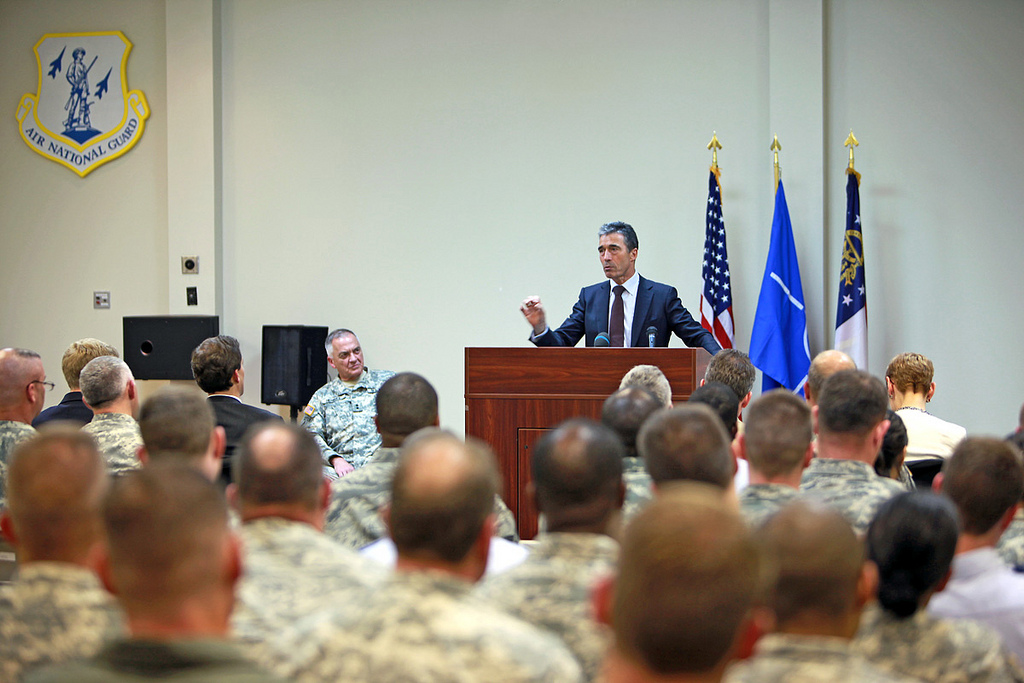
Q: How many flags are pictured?
A: Three.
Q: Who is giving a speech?
A: Man in suit.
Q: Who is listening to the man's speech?
A: Soldiers.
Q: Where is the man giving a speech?
A: Behind a podium.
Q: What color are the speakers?
A: Black.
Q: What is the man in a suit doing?
A: Giving a speech.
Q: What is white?
A: The wall.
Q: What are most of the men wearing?
A: Uniforms.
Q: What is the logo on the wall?
A: Crest.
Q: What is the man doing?
A: Speaking.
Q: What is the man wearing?
A: Suit.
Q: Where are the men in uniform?
A: All over.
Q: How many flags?
A: Three.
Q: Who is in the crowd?
A: A group of soldiers.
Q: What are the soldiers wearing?
A: Camouflage.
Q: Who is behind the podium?
A: The man in the suit.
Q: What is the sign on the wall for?
A: The Air National Guard.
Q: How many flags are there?
A: Three.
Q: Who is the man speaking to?
A: A crowd of soldiers.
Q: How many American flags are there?
A: One.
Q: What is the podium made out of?
A: Wood.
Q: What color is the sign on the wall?
A: Yellow, white, and blue.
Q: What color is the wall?
A: White.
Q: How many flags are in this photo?
A: 3.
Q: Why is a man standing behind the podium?
A: He is giving a speech.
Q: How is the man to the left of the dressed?
A: In an army uniform.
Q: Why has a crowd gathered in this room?
A: To listen to a speech.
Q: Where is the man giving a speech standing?
A: Behind a podium.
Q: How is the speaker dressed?
A: In a suit and tie.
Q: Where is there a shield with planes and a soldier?
A: In the top left corner of the photo.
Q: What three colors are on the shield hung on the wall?
A: Black, yellow, and white.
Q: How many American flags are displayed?
A: 1.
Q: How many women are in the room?
A: 0.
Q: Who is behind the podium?
A: A man in a suit.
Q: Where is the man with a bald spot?
A: In the audience.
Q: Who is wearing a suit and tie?
A: The man behind the podium.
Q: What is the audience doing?
A: Listening to the man speaking.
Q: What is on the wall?
A: The Air National Guard crest.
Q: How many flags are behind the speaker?
A: Three.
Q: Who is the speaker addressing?
A: The audience.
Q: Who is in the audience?
A: Soldiers of the United States of America.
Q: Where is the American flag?
A: Behind the man at the podium.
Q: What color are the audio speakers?
A: Black.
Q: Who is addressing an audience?
A: A man.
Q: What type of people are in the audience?
A: Military.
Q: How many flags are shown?
A: Three.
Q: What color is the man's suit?
A: Blue.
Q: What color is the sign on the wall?
A: Yellow, white and blue.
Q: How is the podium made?
A: Of wood.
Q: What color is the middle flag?
A: Teal.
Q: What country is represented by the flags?
A: America.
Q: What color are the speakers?
A: Black.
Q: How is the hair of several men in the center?
A: Balding.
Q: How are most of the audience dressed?
A: In camouflage.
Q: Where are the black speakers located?
A: On the left near the wall.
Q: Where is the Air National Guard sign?
A: On the wall.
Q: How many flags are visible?
A: Three.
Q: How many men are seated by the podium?
A: One.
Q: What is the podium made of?
A: Wood.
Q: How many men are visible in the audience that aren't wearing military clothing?
A: Two.